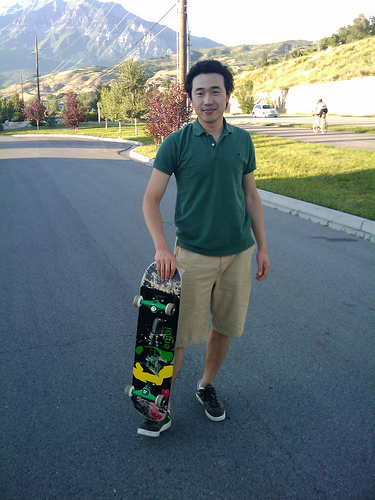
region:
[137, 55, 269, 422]
a man holding a skateboard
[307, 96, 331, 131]
a person riding a bicycle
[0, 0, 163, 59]
a large rocky mountain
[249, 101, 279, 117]
a white parked car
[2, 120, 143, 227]
an aspalt road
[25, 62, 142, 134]
a row of small trees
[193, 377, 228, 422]
a black tennis shoe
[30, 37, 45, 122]
a telephone pole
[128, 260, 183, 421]
a multi colored skate board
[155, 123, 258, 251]
an aqua blue shirt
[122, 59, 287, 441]
Asian man with a skateboard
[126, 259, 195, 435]
black, green and yellow skateboard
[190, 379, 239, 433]
left sneaker of a man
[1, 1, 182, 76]
mountains in the background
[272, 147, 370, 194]
green grass on side of road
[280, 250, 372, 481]
grey street man is standing on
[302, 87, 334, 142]
bicyclist on the sidewalk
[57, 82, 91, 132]
tree with red leaves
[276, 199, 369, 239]
concrete curb by side of road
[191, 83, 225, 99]
eyes of an Asian man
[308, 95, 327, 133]
man riding a bicycle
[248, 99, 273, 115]
white car on the road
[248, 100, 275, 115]
car moving on the street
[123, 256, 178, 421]
skateboard in man's right hand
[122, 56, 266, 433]
skateboarder posing for a picture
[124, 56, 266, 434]
man holding a skateboard standing in the street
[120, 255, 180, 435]
skateboard propped on top of man's foot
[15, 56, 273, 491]
skateboarder standing in the street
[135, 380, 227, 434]
black shoes on skateboarder's feet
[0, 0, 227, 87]
mountains in the photo's background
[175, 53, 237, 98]
Man has dark hair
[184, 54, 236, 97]
Man's hair is black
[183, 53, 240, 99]
Man's hair is curly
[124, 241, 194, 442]
Man carrying skate board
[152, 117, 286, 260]
Man wearing green shirt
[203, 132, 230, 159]
Green shirt has white button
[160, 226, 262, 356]
Man wearing tan shorts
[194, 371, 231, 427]
Man wearing athletic shoe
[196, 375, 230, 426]
Athletic shoe is black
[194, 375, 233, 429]
Athletic shoe has white trim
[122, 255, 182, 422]
a black skateboard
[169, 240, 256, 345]
a pair of khaki shorts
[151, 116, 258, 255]
a green polo shirt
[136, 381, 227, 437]
black skate shoes with white soles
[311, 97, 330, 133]
person riding a bicycle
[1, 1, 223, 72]
large mountain in the background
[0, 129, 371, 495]
street ending in a cul de sac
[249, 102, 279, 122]
a white car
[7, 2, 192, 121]
telephone lines in the background